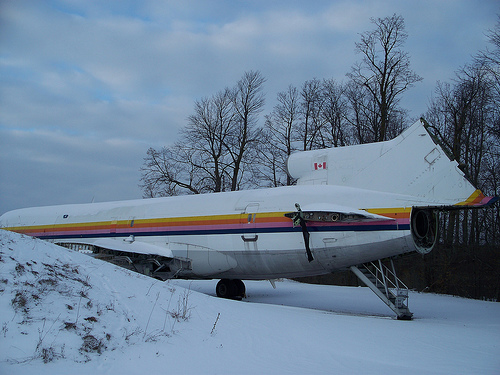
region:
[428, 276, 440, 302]
part of a snow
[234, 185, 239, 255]
part of a plane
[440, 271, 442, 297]
part of a bush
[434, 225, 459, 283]
part of a forest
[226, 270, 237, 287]
part of a wheel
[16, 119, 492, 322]
abandoned airplane in the snow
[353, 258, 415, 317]
ladder up to the airplane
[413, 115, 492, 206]
the airplane's missing tail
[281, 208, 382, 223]
the spot of the airplane's missing tail wing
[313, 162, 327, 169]
a Canadian flag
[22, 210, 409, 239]
purple, pink, orange and yellow stripes on the plane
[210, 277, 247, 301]
the plane's wheel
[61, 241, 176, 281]
the place where the wing used to attach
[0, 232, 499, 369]
the snow-covered ground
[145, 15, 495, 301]
trees behind the abandoned plane fuselage.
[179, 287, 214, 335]
white snow on ground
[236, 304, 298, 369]
white snow on ground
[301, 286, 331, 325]
white snow on ground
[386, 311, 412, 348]
white snow on ground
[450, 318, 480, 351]
white snow on ground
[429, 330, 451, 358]
white snow on ground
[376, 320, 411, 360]
white snow on ground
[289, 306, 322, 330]
white snow on ground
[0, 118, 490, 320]
plane on the ground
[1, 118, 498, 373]
plane is parked in snow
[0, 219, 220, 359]
sticks coming out of snow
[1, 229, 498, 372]
snow on the ground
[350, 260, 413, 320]
the ladder is down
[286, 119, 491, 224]
tail sections are missing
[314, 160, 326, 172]
canadian flag on plane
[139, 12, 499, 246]
no leaves on the trees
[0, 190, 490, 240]
colored stripes on plane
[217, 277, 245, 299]
the wheel is black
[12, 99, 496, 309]
a white plane in snow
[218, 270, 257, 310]
a wheel of the plane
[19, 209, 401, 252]
stripes going down middle of plane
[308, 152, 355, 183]
canadian flag on plane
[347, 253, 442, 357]
steps coming out of plane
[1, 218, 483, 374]
snow covers the ground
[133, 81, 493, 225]
several trees on other side of plane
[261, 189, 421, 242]
broken off wing on back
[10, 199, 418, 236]
yellow and orange stripe on plane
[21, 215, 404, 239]
pink stripe on plane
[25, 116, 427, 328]
this is an airplane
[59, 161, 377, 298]
the airplane is large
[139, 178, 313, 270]
the plane is white and orange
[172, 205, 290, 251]
the stripes are colorful